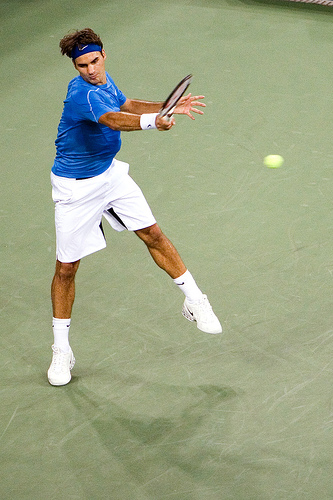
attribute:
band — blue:
[68, 46, 102, 58]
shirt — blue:
[51, 72, 126, 181]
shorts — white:
[51, 157, 157, 263]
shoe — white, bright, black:
[46, 296, 223, 387]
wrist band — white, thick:
[139, 113, 156, 132]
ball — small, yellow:
[266, 155, 284, 169]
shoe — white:
[45, 345, 75, 385]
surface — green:
[1, 1, 332, 500]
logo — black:
[174, 281, 184, 287]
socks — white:
[52, 268, 205, 344]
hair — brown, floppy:
[58, 28, 102, 58]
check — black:
[183, 303, 193, 316]